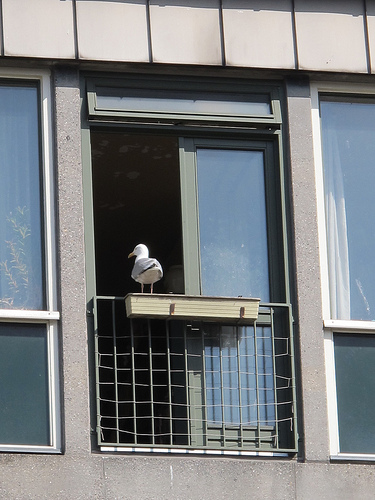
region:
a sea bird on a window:
[123, 239, 166, 299]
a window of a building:
[71, 77, 314, 463]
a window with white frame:
[4, 66, 69, 458]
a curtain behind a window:
[307, 77, 371, 452]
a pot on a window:
[114, 282, 268, 331]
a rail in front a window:
[85, 281, 302, 463]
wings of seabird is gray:
[124, 252, 165, 278]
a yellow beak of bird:
[124, 247, 133, 258]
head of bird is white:
[123, 236, 148, 257]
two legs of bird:
[136, 275, 157, 299]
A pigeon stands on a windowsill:
[122, 235, 162, 295]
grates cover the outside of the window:
[85, 300, 300, 458]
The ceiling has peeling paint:
[93, 130, 168, 202]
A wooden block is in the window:
[120, 288, 265, 322]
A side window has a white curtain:
[302, 93, 370, 318]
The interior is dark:
[90, 129, 176, 232]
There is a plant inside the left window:
[2, 206, 48, 312]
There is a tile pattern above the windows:
[5, 8, 367, 81]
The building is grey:
[290, 97, 316, 233]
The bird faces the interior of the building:
[123, 235, 169, 292]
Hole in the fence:
[96, 349, 121, 367]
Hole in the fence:
[97, 363, 118, 394]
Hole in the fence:
[95, 381, 118, 402]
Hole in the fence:
[91, 397, 118, 422]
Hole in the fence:
[99, 415, 122, 432]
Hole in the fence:
[115, 410, 139, 436]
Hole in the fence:
[128, 380, 158, 405]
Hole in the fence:
[145, 346, 175, 374]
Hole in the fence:
[161, 333, 191, 360]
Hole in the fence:
[197, 333, 224, 363]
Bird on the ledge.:
[113, 227, 229, 316]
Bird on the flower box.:
[122, 237, 319, 361]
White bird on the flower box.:
[120, 230, 259, 334]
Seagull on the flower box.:
[110, 219, 238, 342]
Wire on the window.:
[88, 305, 295, 442]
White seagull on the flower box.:
[77, 225, 291, 353]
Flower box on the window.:
[116, 281, 260, 325]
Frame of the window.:
[2, 285, 84, 362]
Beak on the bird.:
[106, 243, 155, 262]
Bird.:
[106, 207, 231, 345]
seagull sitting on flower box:
[126, 245, 168, 296]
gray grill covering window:
[103, 307, 211, 435]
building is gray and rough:
[100, 465, 138, 495]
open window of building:
[88, 285, 279, 468]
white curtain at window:
[336, 291, 355, 325]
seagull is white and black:
[124, 241, 156, 283]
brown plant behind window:
[8, 290, 40, 300]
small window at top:
[91, 106, 260, 155]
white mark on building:
[159, 466, 190, 485]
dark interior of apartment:
[132, 196, 155, 234]